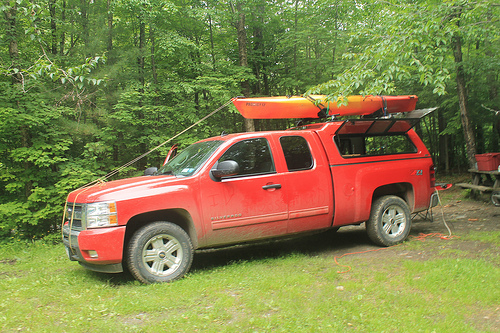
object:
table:
[455, 169, 499, 200]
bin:
[474, 151, 499, 173]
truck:
[61, 96, 454, 286]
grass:
[205, 261, 458, 321]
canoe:
[229, 91, 421, 122]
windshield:
[155, 140, 222, 176]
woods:
[38, 16, 417, 94]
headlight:
[83, 201, 124, 229]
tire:
[123, 220, 195, 287]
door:
[224, 177, 300, 230]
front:
[21, 174, 148, 316]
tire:
[366, 192, 413, 247]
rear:
[404, 121, 442, 213]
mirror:
[208, 160, 247, 181]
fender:
[52, 232, 123, 263]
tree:
[81, 0, 140, 178]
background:
[0, 11, 495, 209]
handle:
[263, 183, 280, 189]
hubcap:
[387, 211, 405, 233]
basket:
[462, 148, 498, 179]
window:
[280, 134, 313, 171]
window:
[213, 137, 277, 177]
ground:
[415, 187, 499, 332]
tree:
[439, 10, 500, 170]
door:
[412, 127, 433, 197]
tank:
[344, 179, 364, 204]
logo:
[61, 215, 72, 229]